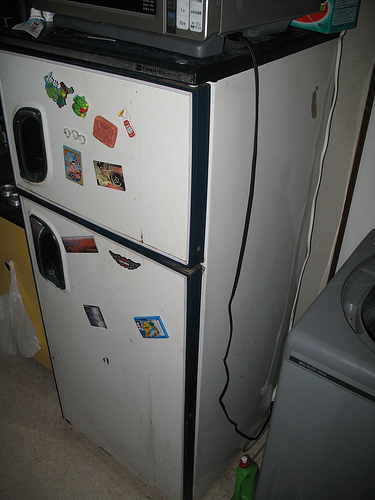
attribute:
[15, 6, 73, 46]
toothpaste — empty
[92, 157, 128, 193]
rectangular magnet — Colorful 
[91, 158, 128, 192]
colorful magnet — Rectangular 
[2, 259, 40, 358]
plastic bag — white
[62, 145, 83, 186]
magnet — colorful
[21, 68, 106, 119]
stickers — green 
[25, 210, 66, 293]
door handle — Black 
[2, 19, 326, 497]
fridge — White 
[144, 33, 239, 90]
magnet — Colorful 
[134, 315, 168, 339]
magnet — colorful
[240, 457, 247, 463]
cap — White 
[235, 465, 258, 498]
green bottle — Green 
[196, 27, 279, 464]
cord — long, black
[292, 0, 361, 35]
soap box — behind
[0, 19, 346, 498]
refrigerator — small, white, metal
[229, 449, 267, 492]
detergent bottle — green 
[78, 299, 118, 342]
magnet — rectangular, colorful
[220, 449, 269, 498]
bottle — green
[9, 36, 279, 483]
refrigerator — White 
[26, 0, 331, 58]
microwave — silver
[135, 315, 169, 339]
sticker — Blue